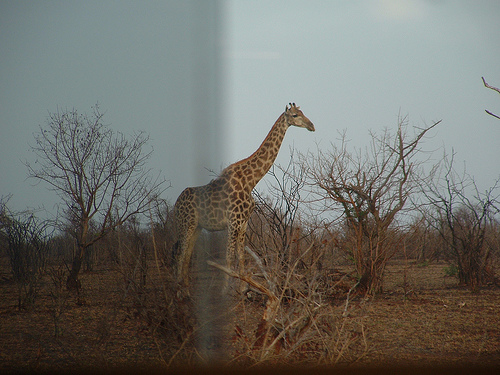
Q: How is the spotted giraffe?
A: Tan and brown.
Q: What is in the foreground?
A: Brown tall bushes on the ground.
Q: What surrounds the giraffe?
A: Tall brown pointy trees.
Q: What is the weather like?
A: Gray sky, no clouds.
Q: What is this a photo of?
A: A giraffe.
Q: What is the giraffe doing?
A: Standing in the tall grass.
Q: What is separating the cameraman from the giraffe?
A: A window.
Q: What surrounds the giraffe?
A: Dead trees.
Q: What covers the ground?
A: Dirt.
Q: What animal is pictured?
A: Giraffe.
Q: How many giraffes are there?
A: One.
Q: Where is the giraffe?
A: In a field.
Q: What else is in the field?
A: Trees.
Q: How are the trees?
A: Bare.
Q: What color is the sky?
A: Greyish-blue.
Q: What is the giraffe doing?
A: Standing.